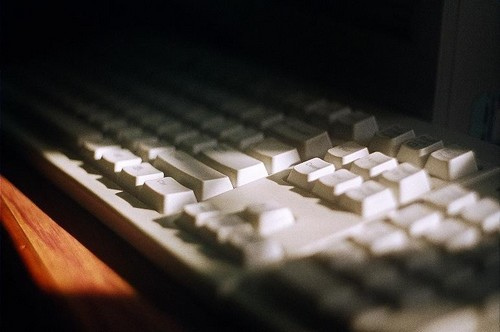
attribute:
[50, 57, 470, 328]
keyboard — white, plastic, dark, edge, part, clean, upper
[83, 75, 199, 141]
keys — in a row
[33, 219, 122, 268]
table — wood, part, small, brown, edge, side, top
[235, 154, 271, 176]
button — part, edge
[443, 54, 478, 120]
shade — edge, part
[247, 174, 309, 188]
sun — shining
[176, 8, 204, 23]
shadow — dark